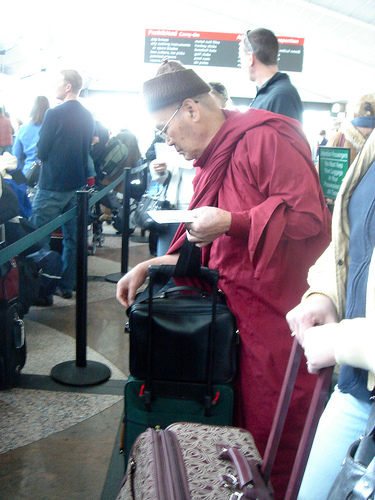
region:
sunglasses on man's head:
[236, 29, 260, 52]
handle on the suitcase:
[219, 443, 257, 497]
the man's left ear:
[177, 101, 208, 121]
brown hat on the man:
[139, 61, 221, 109]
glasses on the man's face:
[155, 112, 178, 142]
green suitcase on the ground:
[120, 375, 234, 427]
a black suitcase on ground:
[127, 267, 236, 382]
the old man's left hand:
[189, 208, 234, 247]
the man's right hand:
[114, 257, 149, 305]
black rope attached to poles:
[0, 164, 135, 279]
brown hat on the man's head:
[147, 51, 213, 113]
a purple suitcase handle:
[264, 330, 335, 492]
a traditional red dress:
[181, 110, 324, 470]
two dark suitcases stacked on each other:
[114, 263, 234, 431]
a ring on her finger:
[290, 329, 298, 337]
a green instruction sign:
[318, 144, 351, 199]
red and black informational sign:
[144, 27, 304, 70]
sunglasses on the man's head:
[241, 26, 258, 52]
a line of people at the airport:
[5, 70, 125, 355]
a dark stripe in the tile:
[7, 371, 125, 396]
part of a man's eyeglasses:
[151, 105, 185, 147]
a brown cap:
[139, 59, 210, 109]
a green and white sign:
[316, 144, 348, 199]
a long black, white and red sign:
[142, 25, 305, 74]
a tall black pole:
[50, 184, 118, 390]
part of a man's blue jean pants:
[31, 181, 80, 290]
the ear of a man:
[244, 48, 255, 67]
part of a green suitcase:
[121, 379, 235, 457]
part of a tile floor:
[1, 387, 125, 498]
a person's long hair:
[27, 95, 49, 127]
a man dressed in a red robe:
[117, 59, 328, 496]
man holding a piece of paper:
[114, 59, 332, 498]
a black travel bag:
[120, 263, 236, 381]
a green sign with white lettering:
[315, 144, 350, 202]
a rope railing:
[0, 160, 153, 391]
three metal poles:
[1, 158, 151, 386]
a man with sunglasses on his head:
[245, 27, 304, 108]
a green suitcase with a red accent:
[119, 373, 236, 470]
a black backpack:
[17, 249, 60, 306]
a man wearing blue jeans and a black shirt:
[32, 67, 92, 301]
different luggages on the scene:
[105, 265, 261, 496]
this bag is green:
[119, 374, 230, 421]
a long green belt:
[6, 160, 125, 240]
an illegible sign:
[145, 28, 235, 66]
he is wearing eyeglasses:
[152, 107, 180, 142]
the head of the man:
[235, 29, 280, 80]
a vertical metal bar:
[62, 194, 99, 366]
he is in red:
[212, 105, 307, 301]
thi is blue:
[36, 99, 89, 192]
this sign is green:
[317, 145, 349, 197]